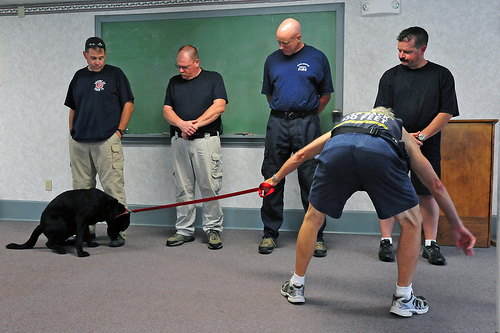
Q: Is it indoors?
A: Yes, it is indoors.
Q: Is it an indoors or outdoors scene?
A: It is indoors.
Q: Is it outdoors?
A: No, it is indoors.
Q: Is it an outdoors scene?
A: No, it is indoors.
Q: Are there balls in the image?
A: No, there are no balls.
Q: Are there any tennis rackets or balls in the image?
A: No, there are no balls or tennis rackets.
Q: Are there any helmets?
A: No, there are no helmets.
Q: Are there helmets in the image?
A: No, there are no helmets.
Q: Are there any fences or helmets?
A: No, there are no helmets or fences.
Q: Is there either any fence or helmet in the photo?
A: No, there are no helmets or fences.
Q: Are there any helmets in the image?
A: No, there are no helmets.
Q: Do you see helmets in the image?
A: No, there are no helmets.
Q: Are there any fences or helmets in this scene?
A: No, there are no helmets or fences.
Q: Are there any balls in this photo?
A: No, there are no balls.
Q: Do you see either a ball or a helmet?
A: No, there are no balls or helmets.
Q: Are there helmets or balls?
A: No, there are no balls or helmets.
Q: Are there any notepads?
A: No, there are no notepads.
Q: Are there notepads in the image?
A: No, there are no notepads.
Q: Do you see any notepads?
A: No, there are no notepads.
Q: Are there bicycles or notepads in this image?
A: No, there are no notepads or bicycles.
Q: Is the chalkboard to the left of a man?
A: Yes, the chalkboard is to the left of a man.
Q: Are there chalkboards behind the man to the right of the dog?
A: Yes, there is a chalkboard behind the man.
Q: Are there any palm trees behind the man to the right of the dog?
A: No, there is a chalkboard behind the man.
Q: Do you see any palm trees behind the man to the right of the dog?
A: No, there is a chalkboard behind the man.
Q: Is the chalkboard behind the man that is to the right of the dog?
A: Yes, the chalkboard is behind the man.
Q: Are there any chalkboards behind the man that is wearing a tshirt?
A: Yes, there is a chalkboard behind the man.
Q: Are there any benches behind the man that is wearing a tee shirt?
A: No, there is a chalkboard behind the man.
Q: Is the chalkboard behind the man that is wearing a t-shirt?
A: Yes, the chalkboard is behind the man.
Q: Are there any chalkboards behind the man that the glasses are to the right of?
A: Yes, there is a chalkboard behind the man.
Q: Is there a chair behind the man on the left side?
A: No, there is a chalkboard behind the man.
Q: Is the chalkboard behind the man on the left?
A: Yes, the chalkboard is behind the man.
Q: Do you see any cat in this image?
A: No, there are no cats.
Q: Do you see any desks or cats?
A: No, there are no cats or desks.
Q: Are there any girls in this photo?
A: No, there are no girls.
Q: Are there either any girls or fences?
A: No, there are no girls or fences.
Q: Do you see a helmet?
A: No, there are no helmets.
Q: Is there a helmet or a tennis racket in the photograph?
A: No, there are no helmets or rackets.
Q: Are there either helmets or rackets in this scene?
A: No, there are no helmets or rackets.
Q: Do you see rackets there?
A: No, there are no rackets.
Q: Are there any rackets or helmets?
A: No, there are no rackets or helmets.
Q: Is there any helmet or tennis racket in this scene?
A: No, there are no rackets or helmets.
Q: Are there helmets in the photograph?
A: No, there are no helmets.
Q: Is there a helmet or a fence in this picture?
A: No, there are no helmets or fences.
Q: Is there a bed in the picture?
A: No, there are no beds.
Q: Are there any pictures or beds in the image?
A: No, there are no beds or pictures.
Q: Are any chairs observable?
A: No, there are no chairs.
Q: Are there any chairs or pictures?
A: No, there are no chairs or pictures.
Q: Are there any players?
A: No, there are no players.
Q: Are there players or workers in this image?
A: No, there are no players or workers.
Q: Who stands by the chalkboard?
A: The man stands by the chalkboard.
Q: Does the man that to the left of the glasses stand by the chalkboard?
A: Yes, the man stands by the chalkboard.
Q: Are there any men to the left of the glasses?
A: Yes, there is a man to the left of the glasses.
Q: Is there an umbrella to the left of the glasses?
A: No, there is a man to the left of the glasses.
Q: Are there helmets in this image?
A: No, there are no helmets.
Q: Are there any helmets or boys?
A: No, there are no helmets or boys.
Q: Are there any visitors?
A: No, there are no visitors.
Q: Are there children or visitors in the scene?
A: No, there are no visitors or children.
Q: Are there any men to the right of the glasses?
A: Yes, there is a man to the right of the glasses.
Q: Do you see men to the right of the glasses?
A: Yes, there is a man to the right of the glasses.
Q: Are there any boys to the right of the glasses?
A: No, there is a man to the right of the glasses.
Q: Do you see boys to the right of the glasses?
A: No, there is a man to the right of the glasses.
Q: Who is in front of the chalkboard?
A: The man is in front of the chalkboard.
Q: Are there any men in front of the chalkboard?
A: Yes, there is a man in front of the chalkboard.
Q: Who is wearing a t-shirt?
A: The man is wearing a t-shirt.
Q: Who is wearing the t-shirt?
A: The man is wearing a t-shirt.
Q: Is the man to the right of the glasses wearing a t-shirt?
A: Yes, the man is wearing a t-shirt.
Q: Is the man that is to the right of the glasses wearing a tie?
A: No, the man is wearing a t-shirt.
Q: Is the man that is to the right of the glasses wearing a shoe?
A: Yes, the man is wearing a shoe.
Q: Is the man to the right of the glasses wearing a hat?
A: No, the man is wearing a shoe.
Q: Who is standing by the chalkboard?
A: The man is standing by the chalkboard.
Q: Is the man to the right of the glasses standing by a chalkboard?
A: Yes, the man is standing by a chalkboard.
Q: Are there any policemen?
A: No, there are no policemen.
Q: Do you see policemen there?
A: No, there are no policemen.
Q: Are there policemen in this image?
A: No, there are no policemen.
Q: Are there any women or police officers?
A: No, there are no police officers or women.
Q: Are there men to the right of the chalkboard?
A: Yes, there is a man to the right of the chalkboard.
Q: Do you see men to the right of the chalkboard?
A: Yes, there is a man to the right of the chalkboard.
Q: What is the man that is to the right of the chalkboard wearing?
A: The man is wearing a shoe.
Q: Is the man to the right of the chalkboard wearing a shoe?
A: Yes, the man is wearing a shoe.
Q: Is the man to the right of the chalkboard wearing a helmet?
A: No, the man is wearing a shoe.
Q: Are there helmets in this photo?
A: No, there are no helmets.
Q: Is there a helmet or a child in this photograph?
A: No, there are no helmets or children.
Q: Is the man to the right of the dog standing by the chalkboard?
A: Yes, the man is standing by the chalkboard.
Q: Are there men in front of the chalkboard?
A: Yes, there is a man in front of the chalkboard.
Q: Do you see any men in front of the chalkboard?
A: Yes, there is a man in front of the chalkboard.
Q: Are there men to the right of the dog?
A: Yes, there is a man to the right of the dog.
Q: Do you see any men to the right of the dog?
A: Yes, there is a man to the right of the dog.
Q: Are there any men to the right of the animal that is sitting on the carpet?
A: Yes, there is a man to the right of the dog.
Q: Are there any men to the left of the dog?
A: No, the man is to the right of the dog.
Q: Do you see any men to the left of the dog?
A: No, the man is to the right of the dog.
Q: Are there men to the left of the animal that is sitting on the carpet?
A: No, the man is to the right of the dog.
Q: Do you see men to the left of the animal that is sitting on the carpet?
A: No, the man is to the right of the dog.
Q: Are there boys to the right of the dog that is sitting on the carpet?
A: No, there is a man to the right of the dog.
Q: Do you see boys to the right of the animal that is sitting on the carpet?
A: No, there is a man to the right of the dog.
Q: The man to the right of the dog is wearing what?
A: The man is wearing a shoe.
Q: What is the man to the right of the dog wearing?
A: The man is wearing a shoe.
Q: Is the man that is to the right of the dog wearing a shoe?
A: Yes, the man is wearing a shoe.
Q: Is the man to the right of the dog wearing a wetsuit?
A: No, the man is wearing a shoe.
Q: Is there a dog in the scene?
A: Yes, there is a dog.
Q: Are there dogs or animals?
A: Yes, there is a dog.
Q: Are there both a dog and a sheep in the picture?
A: No, there is a dog but no sheep.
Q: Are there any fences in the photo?
A: No, there are no fences.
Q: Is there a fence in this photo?
A: No, there are no fences.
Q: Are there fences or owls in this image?
A: No, there are no fences or owls.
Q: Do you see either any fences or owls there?
A: No, there are no fences or owls.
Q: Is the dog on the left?
A: Yes, the dog is on the left of the image.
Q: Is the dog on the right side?
A: No, the dog is on the left of the image.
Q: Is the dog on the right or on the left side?
A: The dog is on the left of the image.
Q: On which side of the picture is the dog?
A: The dog is on the left of the image.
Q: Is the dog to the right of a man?
A: No, the dog is to the left of a man.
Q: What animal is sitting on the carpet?
A: The dog is sitting on the carpet.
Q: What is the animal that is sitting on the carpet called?
A: The animal is a dog.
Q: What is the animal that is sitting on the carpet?
A: The animal is a dog.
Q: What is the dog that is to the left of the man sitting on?
A: The dog is sitting on the carpet.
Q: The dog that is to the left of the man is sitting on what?
A: The dog is sitting on the carpet.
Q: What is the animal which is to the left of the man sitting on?
A: The dog is sitting on the carpet.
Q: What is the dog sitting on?
A: The dog is sitting on the carpet.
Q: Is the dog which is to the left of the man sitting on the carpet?
A: Yes, the dog is sitting on the carpet.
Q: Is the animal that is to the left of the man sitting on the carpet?
A: Yes, the dog is sitting on the carpet.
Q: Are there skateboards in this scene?
A: No, there are no skateboards.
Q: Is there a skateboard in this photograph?
A: No, there are no skateboards.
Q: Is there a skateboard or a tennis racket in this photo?
A: No, there are no skateboards or rackets.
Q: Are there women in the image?
A: No, there are no women.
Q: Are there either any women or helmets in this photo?
A: No, there are no women or helmets.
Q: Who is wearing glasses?
A: The man is wearing glasses.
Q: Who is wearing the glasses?
A: The man is wearing glasses.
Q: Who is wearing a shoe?
A: The man is wearing a shoe.